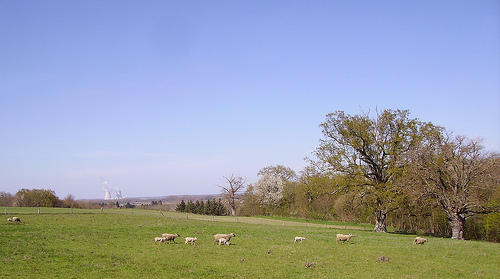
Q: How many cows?
A: Ten.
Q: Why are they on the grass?
A: Eating.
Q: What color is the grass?
A: Green.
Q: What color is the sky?
A: Blue.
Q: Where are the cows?
A: Field.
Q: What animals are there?
A: Cows.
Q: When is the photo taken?
A: Daytime.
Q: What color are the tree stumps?
A: Brown.